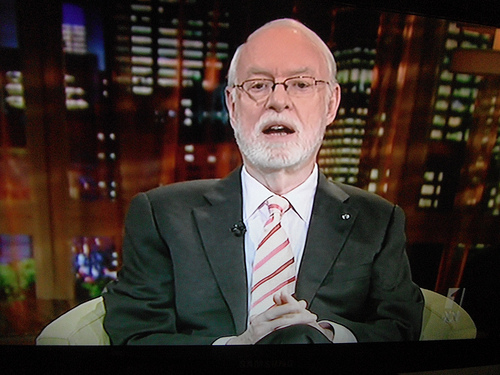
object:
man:
[98, 17, 425, 344]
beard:
[229, 113, 322, 170]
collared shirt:
[233, 163, 315, 330]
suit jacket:
[102, 165, 425, 348]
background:
[1, 1, 498, 348]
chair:
[36, 269, 476, 345]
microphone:
[228, 221, 246, 235]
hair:
[227, 18, 333, 86]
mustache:
[256, 113, 298, 131]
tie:
[248, 193, 298, 332]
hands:
[238, 291, 319, 346]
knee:
[255, 322, 329, 343]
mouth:
[257, 120, 296, 142]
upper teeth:
[269, 124, 287, 129]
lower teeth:
[269, 131, 286, 136]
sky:
[2, 1, 107, 72]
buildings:
[1, 1, 499, 337]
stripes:
[249, 255, 298, 297]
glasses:
[230, 75, 334, 93]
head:
[221, 18, 340, 170]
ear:
[325, 84, 340, 126]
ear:
[222, 85, 237, 123]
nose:
[263, 81, 292, 113]